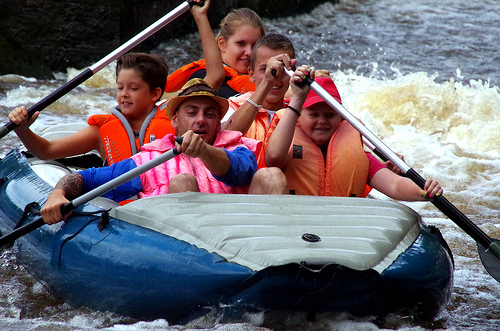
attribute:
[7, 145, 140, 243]
handle — silver, black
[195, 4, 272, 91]
girl — rafting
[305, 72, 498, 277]
paddle — black, silver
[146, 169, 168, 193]
vest — pink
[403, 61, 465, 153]
wave — turbulent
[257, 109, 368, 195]
vest — orange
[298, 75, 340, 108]
hat — red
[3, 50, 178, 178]
boy — young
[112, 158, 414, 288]
raft — grey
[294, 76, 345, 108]
hat — red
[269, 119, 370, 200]
vest — orange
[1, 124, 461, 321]
raft — grey, blue, inflatable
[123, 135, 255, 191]
jacket — pink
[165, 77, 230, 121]
hat — tan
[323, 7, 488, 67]
water — calm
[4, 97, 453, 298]
raft — blue, grey, inflatable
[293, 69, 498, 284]
paddle — black, silver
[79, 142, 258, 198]
shirt — blue